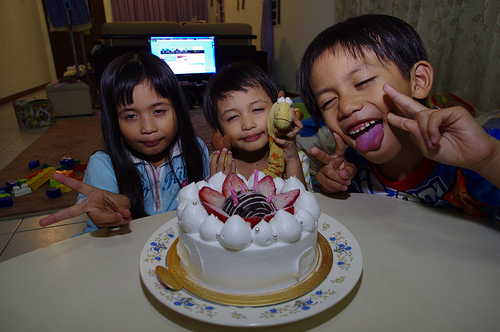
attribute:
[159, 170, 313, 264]
cake — white, fronted, decorated, red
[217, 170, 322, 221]
icing — flower, white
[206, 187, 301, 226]
flower — strawberries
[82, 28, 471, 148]
students — sitting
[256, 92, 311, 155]
child — holding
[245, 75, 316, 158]
kid — holding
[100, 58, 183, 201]
girl — showing, little, holding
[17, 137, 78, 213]
toys — large, multicolored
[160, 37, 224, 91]
screen — on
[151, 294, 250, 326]
plate — white, floral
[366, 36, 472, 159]
kid — making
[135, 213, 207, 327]
dish — white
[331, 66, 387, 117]
eyes — closed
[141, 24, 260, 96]
laptop — on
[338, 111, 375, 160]
tongue — out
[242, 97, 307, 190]
toys — held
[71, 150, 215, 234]
shirt — blue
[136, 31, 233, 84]
television — on, behind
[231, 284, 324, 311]
platter — gold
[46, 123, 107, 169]
rug — brown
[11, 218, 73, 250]
tiles — large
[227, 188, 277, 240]
strawberry — cut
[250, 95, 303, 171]
giraffe — toy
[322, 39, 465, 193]
boy — holding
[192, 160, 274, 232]
strawberries — sliced